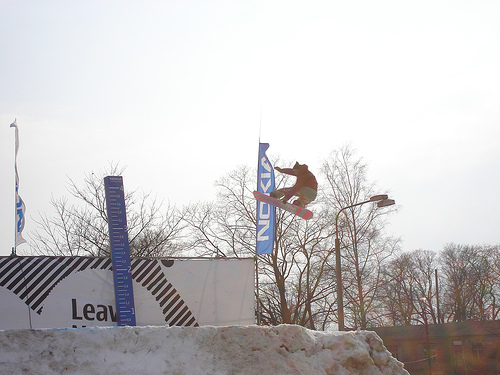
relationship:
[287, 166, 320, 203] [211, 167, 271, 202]
person doing tricks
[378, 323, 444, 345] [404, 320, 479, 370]
awning on building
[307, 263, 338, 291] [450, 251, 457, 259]
trees without leaves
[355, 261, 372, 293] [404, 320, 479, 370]
pole near building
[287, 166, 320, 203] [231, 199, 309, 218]
person on snowboard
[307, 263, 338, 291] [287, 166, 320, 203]
trees behind person